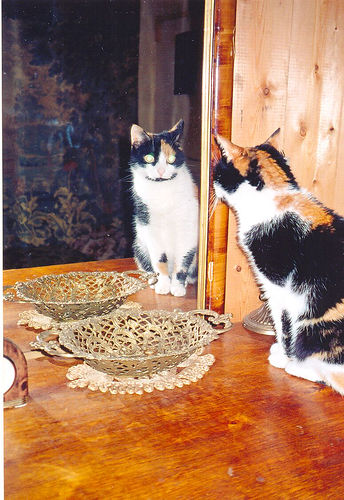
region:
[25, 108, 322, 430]
a cat looking in the mirror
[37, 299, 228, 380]
a golden wicker basket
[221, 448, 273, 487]
scratches a dresser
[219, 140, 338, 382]
a calico colored cat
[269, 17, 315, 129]
wood panels covering the wall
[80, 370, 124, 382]
a knitted coaster under the basker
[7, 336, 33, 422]
a wooden clock sitting on the dresser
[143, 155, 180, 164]
green eyes reflected in the mirror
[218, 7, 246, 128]
the brown wooden frame around the mirror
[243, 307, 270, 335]
the edge of a silver lamp on the dresser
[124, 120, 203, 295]
Reflection of cat in the mirror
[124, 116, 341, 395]
Calico cat looking at reflection in mirror.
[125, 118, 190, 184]
Face of calico cat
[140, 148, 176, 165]
Eyes of cat in reflection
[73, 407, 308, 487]
Wood table pattern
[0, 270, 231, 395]
Bowl and reflection of bowl in mirror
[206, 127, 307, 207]
Back of head of calico cat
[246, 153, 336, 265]
Fur on the back of a cat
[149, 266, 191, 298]
Front paws of a cat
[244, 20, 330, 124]
Wood panel's on the wall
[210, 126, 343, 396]
Cat sits front mirror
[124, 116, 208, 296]
Mirrored image cat scary eyes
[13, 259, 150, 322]
Ornate handled gold dish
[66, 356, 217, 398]
Fancy gold doily protection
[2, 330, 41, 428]
Small wood framed hand mirror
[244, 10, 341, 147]
Wall board knotty pine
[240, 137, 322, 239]
Cat neck fur orange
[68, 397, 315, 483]
Wooden surface many scratches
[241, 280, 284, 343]
Possible table lamp behind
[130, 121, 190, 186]
Mirrored image scares original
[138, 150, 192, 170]
Cat has light colored eyes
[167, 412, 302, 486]
Table is wood and brown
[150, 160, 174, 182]
Cat has white and pink nose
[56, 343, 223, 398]
White doily under basket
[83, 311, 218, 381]
Gray basket on top of doiley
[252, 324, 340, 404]
Cat has white, black, and tan fur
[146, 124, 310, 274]
Cat is looking in mirror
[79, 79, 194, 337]
Reflection of cat in mirror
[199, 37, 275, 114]
Trim of mirror is wood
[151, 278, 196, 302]
Cat has white paws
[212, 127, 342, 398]
calico cat looking in the mirror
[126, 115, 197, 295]
calico cats reflection looking back at the cat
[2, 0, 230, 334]
large dresser mirror with an antique looking frame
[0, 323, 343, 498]
top of dresser with a distressed antique look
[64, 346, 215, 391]
ivory colored crocheted doiley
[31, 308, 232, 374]
lattice work silver bowl with handels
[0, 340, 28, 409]
edge of a clock with a wooden case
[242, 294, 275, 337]
candle stick mostly hidden by cat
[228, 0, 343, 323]
knotty pine wood paneled wall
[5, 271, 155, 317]
reflection of lattice work silver bowl in mirror